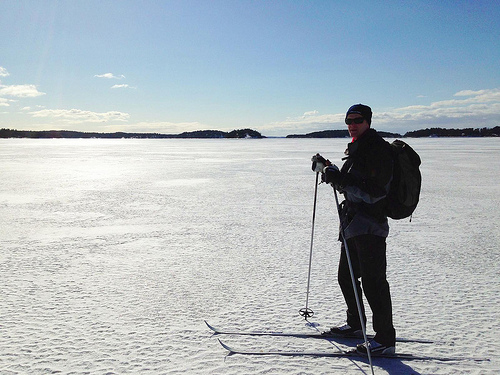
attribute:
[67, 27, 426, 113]
sky — blue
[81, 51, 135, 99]
cloud — white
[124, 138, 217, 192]
snow — white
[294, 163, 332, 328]
skipole — white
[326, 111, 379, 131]
sunglasses — black, dark, worn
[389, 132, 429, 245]
backpack — dark, worn, grey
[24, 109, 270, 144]
tree — here, in distance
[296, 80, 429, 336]
man — here, skiing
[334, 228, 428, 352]
pants — dark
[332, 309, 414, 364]
boots — white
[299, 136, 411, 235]
jacket — dark, grey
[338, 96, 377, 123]
hat — wool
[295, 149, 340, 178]
gloves — black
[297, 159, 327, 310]
pole — held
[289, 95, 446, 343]
person — posing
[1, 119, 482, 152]
horizon — distant